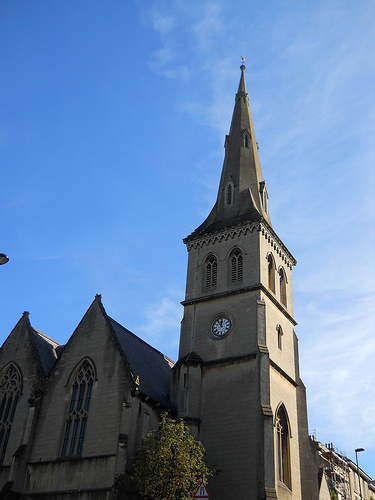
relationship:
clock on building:
[210, 316, 233, 339] [1, 54, 373, 498]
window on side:
[52, 354, 101, 459] [0, 291, 170, 498]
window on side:
[2, 358, 27, 460] [0, 291, 170, 498]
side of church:
[0, 291, 170, 498] [4, 52, 373, 498]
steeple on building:
[170, 54, 307, 497] [1, 54, 373, 498]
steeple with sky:
[170, 54, 307, 497] [4, 4, 374, 476]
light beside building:
[353, 445, 367, 498] [1, 54, 373, 498]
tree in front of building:
[111, 410, 222, 497] [1, 54, 373, 498]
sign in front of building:
[190, 479, 213, 498] [1, 54, 373, 498]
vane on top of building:
[239, 53, 245, 68] [1, 54, 373, 498]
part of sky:
[53, 41, 125, 88] [4, 4, 374, 476]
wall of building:
[174, 227, 274, 497] [1, 54, 373, 498]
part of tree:
[148, 437, 189, 470] [111, 410, 222, 497]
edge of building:
[116, 357, 126, 498] [1, 54, 373, 498]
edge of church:
[253, 295, 278, 498] [4, 52, 373, 498]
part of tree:
[166, 464, 187, 487] [111, 410, 222, 497]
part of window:
[59, 407, 85, 460] [52, 354, 101, 459]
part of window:
[274, 417, 283, 484] [273, 398, 295, 494]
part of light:
[354, 445, 366, 454] [353, 445, 367, 498]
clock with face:
[210, 315, 233, 339] [212, 315, 229, 336]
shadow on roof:
[116, 322, 168, 401] [109, 306, 177, 405]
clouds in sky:
[148, 295, 174, 335] [4, 4, 374, 476]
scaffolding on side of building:
[310, 434, 352, 493] [1, 54, 373, 498]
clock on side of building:
[210, 315, 233, 339] [1, 54, 373, 498]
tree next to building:
[106, 410, 221, 500] [1, 54, 373, 498]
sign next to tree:
[190, 479, 213, 498] [122, 414, 208, 497]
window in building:
[57, 353, 101, 459] [1, 54, 373, 498]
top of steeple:
[186, 51, 273, 224] [170, 54, 307, 497]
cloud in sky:
[299, 243, 366, 441] [4, 4, 374, 476]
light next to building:
[353, 445, 367, 498] [1, 54, 373, 498]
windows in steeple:
[195, 241, 249, 288] [170, 54, 307, 497]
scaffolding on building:
[319, 438, 351, 499] [1, 54, 373, 498]